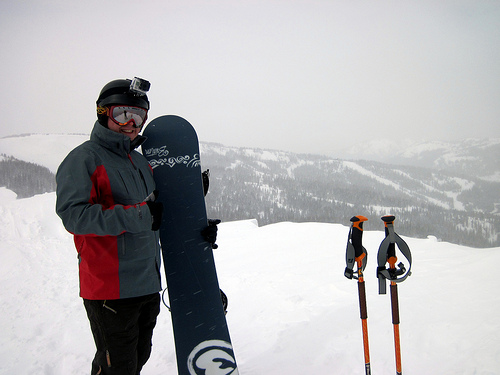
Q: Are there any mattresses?
A: No, there are no mattresses.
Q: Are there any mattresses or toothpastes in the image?
A: No, there are no mattresses or toothpastes.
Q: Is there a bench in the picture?
A: No, there are no benches.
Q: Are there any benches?
A: No, there are no benches.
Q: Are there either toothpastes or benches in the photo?
A: No, there are no benches or toothpastes.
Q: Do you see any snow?
A: Yes, there is snow.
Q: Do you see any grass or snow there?
A: Yes, there is snow.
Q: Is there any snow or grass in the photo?
A: Yes, there is snow.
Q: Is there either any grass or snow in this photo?
A: Yes, there is snow.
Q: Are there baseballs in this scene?
A: No, there are no baseballs.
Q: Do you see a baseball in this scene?
A: No, there are no baseballs.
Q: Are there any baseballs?
A: No, there are no baseballs.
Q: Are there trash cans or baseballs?
A: No, there are no baseballs or trash cans.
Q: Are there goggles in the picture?
A: Yes, there are goggles.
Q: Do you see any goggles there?
A: Yes, there are goggles.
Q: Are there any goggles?
A: Yes, there are goggles.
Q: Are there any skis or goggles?
A: Yes, there are goggles.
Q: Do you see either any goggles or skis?
A: Yes, there are goggles.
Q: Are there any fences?
A: No, there are no fences.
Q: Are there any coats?
A: Yes, there is a coat.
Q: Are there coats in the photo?
A: Yes, there is a coat.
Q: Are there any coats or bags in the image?
A: Yes, there is a coat.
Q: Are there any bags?
A: No, there are no bags.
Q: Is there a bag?
A: No, there are no bags.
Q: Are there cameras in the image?
A: Yes, there is a camera.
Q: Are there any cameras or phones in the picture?
A: Yes, there is a camera.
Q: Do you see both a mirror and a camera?
A: No, there is a camera but no mirrors.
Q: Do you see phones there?
A: No, there are no phones.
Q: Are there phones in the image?
A: No, there are no phones.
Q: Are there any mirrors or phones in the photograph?
A: No, there are no phones or mirrors.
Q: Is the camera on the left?
A: Yes, the camera is on the left of the image.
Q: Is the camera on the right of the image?
A: No, the camera is on the left of the image.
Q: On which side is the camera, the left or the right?
A: The camera is on the left of the image.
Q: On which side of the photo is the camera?
A: The camera is on the left of the image.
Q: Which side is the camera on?
A: The camera is on the left of the image.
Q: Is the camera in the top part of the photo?
A: Yes, the camera is in the top of the image.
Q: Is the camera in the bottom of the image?
A: No, the camera is in the top of the image.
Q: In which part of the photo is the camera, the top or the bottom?
A: The camera is in the top of the image.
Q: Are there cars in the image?
A: No, there are no cars.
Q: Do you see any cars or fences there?
A: No, there are no cars or fences.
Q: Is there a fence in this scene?
A: No, there are no fences.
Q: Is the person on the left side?
A: Yes, the person is on the left of the image.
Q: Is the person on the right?
A: No, the person is on the left of the image.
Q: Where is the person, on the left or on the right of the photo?
A: The person is on the left of the image.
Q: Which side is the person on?
A: The person is on the left of the image.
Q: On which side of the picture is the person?
A: The person is on the left of the image.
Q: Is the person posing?
A: Yes, the person is posing.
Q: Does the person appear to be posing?
A: Yes, the person is posing.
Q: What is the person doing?
A: The person is posing.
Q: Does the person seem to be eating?
A: No, the person is posing.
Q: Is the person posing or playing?
A: The person is posing.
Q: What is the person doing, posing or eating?
A: The person is posing.